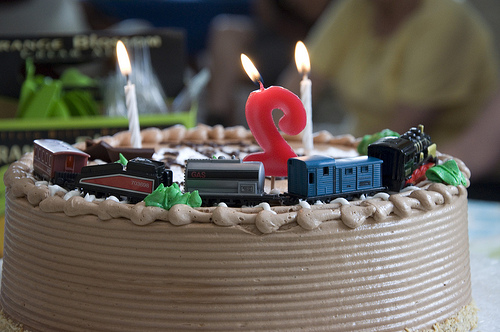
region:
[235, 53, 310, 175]
Red lit up candle.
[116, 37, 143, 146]
A white lit candle.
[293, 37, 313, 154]
A white birthday candle.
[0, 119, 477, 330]
A chocolate frosted cake.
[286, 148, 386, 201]
A blue toy train.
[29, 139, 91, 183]
Little red toy caboose.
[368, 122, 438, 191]
A black toy engine.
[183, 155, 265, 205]
Gray and black tank car.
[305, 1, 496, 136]
Person in a yellow shirt.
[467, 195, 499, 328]
A blue colored tabletop.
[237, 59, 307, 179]
someone's turning two years old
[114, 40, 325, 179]
three candles on top of the cake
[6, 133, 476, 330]
cake with chocolate frosting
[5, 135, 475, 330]
frosting finished with straight lines around the cake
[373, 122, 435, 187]
a model steam train engine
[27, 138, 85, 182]
the train caboose is red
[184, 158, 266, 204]
this model train is carrying a tank of gas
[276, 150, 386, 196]
a model passenger cart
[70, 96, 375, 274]
A birthday cake with chocolate frosting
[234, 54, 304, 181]
A red number two candle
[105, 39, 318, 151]
There are three candles but its for a 2nd birthday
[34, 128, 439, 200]
A train decoration on the cake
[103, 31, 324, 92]
The candles are all lit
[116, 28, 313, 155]
The candles have not been blown out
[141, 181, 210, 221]
Green frosting on the cake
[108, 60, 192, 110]
Plastic forks in the background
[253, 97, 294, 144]
red number two on cake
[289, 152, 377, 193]
blue train on cake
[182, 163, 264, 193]
silver train on cake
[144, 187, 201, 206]
green frosting on cake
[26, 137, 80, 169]
red train on cake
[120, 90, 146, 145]
white candle on cake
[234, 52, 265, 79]
flame on number two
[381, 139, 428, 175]
black train on cake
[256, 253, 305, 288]
vanilla frosting on cake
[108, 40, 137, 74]
flame on white candle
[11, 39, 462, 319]
a two year olds birthday cake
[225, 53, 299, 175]
a number two candle on a cake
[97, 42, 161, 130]
a lit candle on a cake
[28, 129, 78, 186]
a red toy train on a cake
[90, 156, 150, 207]
a black and red toy train on a cake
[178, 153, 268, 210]
a grey toy train on a cake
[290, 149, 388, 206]
a blue toy train on a cake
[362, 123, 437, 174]
a black toy train on a cake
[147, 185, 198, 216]
a bush made out of frosting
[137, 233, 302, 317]
the chocolate frosting on a cake